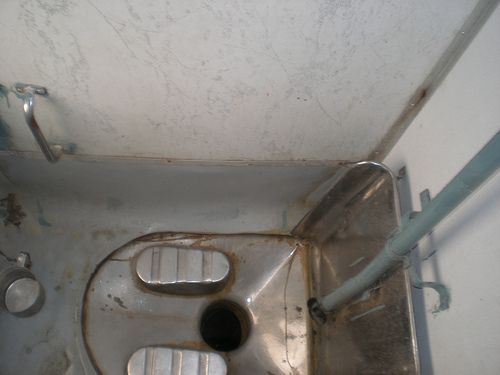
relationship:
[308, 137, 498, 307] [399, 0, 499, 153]
pipe going up wall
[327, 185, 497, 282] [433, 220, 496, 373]
pipe connected to wall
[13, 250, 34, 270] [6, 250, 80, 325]
handle attached to cup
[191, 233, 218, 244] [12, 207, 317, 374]
stain soiling floor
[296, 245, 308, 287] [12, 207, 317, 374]
stain soiling floor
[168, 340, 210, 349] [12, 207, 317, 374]
stain soiling floor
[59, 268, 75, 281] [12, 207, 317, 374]
stain soiling floor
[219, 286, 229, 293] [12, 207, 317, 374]
stain soiling floor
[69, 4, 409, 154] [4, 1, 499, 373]
wall supporting room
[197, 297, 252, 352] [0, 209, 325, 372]
hole built into ground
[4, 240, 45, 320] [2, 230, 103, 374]
cup on ground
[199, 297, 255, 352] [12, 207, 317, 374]
drain in floor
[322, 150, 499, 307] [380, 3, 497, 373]
pipe on wall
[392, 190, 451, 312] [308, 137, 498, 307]
hinge for pipe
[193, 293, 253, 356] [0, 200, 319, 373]
drain on metal floor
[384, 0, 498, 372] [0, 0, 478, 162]
walls meet walls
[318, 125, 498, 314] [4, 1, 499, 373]
pole in room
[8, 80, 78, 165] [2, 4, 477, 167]
bar on wall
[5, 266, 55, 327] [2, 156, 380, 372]
cup on ground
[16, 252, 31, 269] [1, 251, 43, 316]
handle of cup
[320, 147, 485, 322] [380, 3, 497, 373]
pipe up against wall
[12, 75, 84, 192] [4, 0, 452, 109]
handle on wall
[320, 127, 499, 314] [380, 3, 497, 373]
pipe anchored to wall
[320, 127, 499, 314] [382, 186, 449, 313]
pipe anchored with bracket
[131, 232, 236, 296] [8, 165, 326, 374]
foot rest on floor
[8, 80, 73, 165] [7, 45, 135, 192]
handle on wall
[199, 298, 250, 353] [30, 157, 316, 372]
hole in ground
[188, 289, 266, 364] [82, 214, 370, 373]
holes on toilet seat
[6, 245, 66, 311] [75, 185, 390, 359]
cup in front of toilet